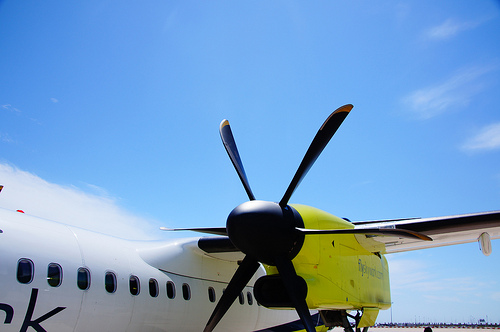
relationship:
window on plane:
[99, 265, 120, 300] [0, 103, 497, 330]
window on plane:
[144, 271, 173, 301] [0, 161, 498, 330]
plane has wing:
[1, 153, 497, 315] [242, 189, 499, 286]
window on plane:
[77, 267, 91, 291] [8, 191, 363, 328]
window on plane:
[16, 258, 36, 286] [8, 191, 363, 328]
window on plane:
[204, 283, 221, 307] [0, 103, 497, 330]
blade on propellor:
[275, 98, 358, 210] [165, 102, 432, 330]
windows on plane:
[17, 254, 197, 314] [4, 156, 440, 330]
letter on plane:
[22, 288, 64, 330] [0, 103, 497, 330]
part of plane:
[260, 202, 391, 307] [0, 103, 497, 330]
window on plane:
[41, 260, 69, 288] [0, 103, 497, 330]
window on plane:
[76, 266, 91, 291] [0, 103, 497, 330]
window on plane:
[104, 270, 119, 294] [0, 103, 497, 330]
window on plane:
[129, 275, 140, 295] [0, 103, 497, 330]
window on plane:
[146, 276, 160, 299] [0, 103, 497, 330]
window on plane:
[166, 280, 176, 299] [0, 103, 497, 330]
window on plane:
[180, 281, 192, 298] [0, 103, 497, 330]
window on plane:
[130, 274, 140, 294] [0, 103, 497, 330]